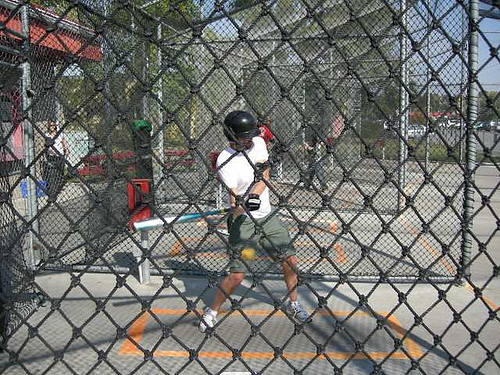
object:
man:
[196, 108, 314, 337]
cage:
[0, 0, 499, 375]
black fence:
[0, 0, 499, 375]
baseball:
[238, 247, 255, 263]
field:
[0, 123, 499, 374]